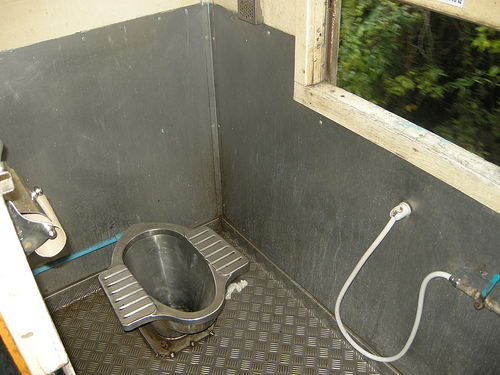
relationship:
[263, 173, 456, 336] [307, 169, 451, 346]
white hose on wall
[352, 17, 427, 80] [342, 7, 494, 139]
green leaves on tree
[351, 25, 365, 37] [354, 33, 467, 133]
leaf on tree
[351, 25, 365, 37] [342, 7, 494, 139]
leaf on tree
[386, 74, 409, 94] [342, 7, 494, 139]
leaves on tree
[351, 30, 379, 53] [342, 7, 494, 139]
leaves on tree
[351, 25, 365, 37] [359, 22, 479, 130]
leaf on tree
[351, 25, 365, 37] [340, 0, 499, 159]
leaf on tree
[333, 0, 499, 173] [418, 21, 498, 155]
leaves on tree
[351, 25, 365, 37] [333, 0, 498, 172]
leaf on tree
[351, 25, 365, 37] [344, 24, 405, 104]
leaf on tree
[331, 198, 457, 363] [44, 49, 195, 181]
cord on wall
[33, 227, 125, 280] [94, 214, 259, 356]
pipe on toilet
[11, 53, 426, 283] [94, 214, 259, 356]
wall by toilet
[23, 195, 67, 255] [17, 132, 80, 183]
toilet paper on wall